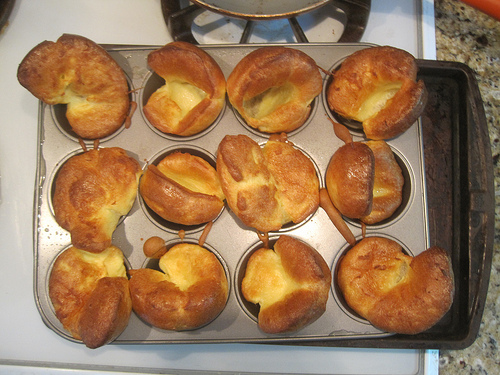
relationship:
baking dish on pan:
[35, 42, 493, 348] [248, 38, 484, 349]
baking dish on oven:
[35, 42, 493, 348] [0, 0, 443, 373]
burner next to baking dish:
[153, 0, 371, 48] [35, 42, 493, 348]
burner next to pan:
[153, 0, 371, 48] [230, 52, 494, 352]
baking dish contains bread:
[35, 42, 493, 348] [326, 48, 427, 142]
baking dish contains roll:
[35, 42, 493, 348] [330, 146, 391, 213]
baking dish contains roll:
[35, 42, 493, 348] [333, 229, 451, 333]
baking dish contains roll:
[35, 42, 493, 348] [326, 46, 418, 130]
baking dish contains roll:
[35, 42, 493, 348] [230, 236, 332, 340]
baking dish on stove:
[35, 42, 493, 348] [1, 3, 456, 371]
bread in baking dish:
[326, 48, 427, 142] [35, 42, 493, 348]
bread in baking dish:
[322, 141, 404, 225] [35, 42, 493, 348]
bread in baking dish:
[335, 234, 455, 336] [35, 42, 493, 348]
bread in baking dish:
[241, 234, 331, 338] [35, 42, 493, 348]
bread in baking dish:
[216, 131, 318, 237] [35, 42, 493, 348]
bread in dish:
[326, 48, 427, 142] [31, 37, 431, 344]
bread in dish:
[220, 45, 321, 135] [31, 37, 431, 344]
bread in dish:
[216, 131, 318, 237] [31, 37, 431, 344]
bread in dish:
[241, 234, 331, 338] [31, 37, 431, 344]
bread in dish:
[124, 235, 228, 328] [31, 37, 431, 344]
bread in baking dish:
[17, 34, 128, 139] [35, 42, 493, 348]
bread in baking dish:
[143, 40, 225, 136] [35, 42, 493, 348]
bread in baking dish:
[220, 45, 321, 135] [35, 42, 493, 348]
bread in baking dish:
[50, 145, 141, 253] [35, 42, 493, 348]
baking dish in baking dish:
[35, 42, 493, 348] [237, 59, 494, 350]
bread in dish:
[50, 145, 141, 253] [31, 37, 431, 344]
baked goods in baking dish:
[33, 29, 441, 347] [35, 42, 493, 348]